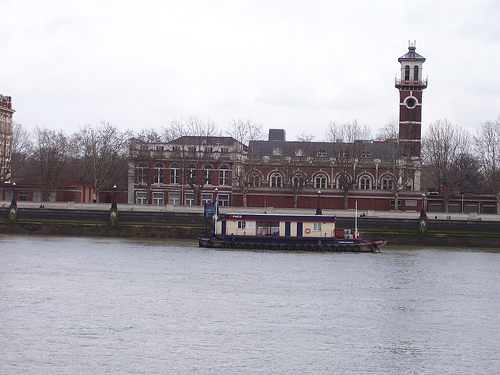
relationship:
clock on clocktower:
[404, 97, 421, 108] [394, 39, 426, 167]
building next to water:
[117, 35, 428, 236] [2, 246, 495, 373]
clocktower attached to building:
[396, 43, 422, 139] [117, 35, 428, 236]